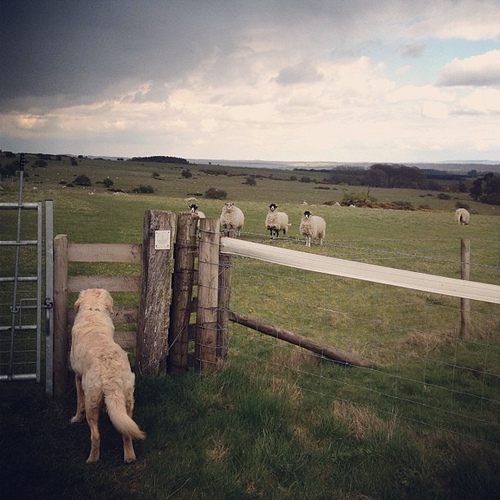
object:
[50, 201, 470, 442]
fence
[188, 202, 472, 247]
sheep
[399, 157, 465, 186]
ground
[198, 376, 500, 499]
ground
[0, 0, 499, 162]
cloudy sky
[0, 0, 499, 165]
sky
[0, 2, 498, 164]
clouds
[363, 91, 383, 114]
ground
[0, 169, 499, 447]
gate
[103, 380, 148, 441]
tail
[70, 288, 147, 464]
dog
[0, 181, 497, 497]
grass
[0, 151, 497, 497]
field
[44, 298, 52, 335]
lock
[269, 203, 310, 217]
faces